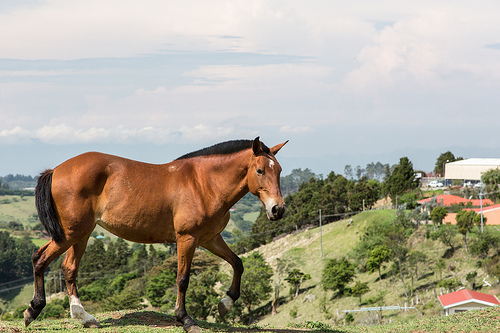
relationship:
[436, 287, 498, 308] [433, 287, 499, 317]
red roof on a building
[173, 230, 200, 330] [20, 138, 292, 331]
leg of horse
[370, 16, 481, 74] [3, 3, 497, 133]
clouds in sky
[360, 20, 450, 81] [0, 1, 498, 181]
clouds in sky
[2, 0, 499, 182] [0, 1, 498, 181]
clouds in sky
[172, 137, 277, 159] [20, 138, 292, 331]
black hair on horse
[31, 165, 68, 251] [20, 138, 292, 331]
tail on horse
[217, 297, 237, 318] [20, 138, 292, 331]
hoof on horse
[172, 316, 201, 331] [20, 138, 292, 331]
hoof on horse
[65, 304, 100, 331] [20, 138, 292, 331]
hoof on horse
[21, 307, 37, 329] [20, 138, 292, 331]
hoof on horse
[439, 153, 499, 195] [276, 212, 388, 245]
building on top of hill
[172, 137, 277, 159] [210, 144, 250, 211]
black hair running down neck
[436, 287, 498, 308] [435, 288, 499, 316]
red roof of house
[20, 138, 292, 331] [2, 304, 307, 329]
horse on field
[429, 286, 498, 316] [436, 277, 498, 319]
house with roof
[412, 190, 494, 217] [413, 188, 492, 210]
house with red roof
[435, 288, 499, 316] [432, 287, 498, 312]
house with red roof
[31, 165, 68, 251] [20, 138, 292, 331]
tail of horse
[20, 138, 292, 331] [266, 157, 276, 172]
horse has spot